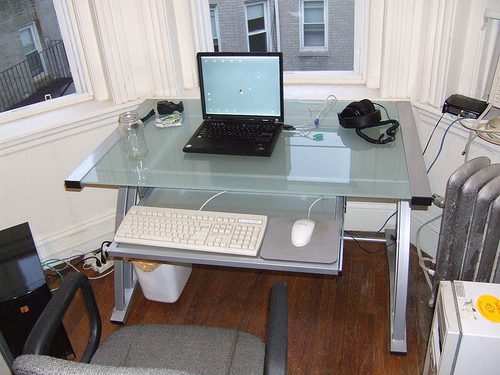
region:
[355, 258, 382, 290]
Dark brown wood grain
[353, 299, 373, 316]
Dark brown wood grain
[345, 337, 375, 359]
Dark brown wood grain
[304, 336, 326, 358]
Dark brown wood grain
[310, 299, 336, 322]
Dark brown wood grain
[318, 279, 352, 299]
Dark brown wood grain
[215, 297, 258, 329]
Dark brown wood grain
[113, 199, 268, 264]
White keyboard with white keys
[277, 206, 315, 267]
White mouse on grey mousepad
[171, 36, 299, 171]
Small black laptop computer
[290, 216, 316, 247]
a white computer mouse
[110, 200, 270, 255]
a white computer keyboard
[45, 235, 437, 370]
part of a brown hardwood floor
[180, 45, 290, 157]
a black laptop computer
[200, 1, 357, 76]
part of a window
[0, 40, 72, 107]
part of a balcony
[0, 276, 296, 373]
a gray and black computer chair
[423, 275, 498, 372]
part of a computer cpu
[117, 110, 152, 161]
a tall clear jar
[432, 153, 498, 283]
part of a gray wall heater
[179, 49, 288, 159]
Black laptop with blue desktop screen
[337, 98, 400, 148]
Pair of black computer headphones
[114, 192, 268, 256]
Corded white computer keyboard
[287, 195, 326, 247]
Corded white computer mouse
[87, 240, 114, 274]
White surge protector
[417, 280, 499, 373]
White central processing unit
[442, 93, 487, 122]
Black internet router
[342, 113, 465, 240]
Long blue ethernet cord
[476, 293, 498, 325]
Oval yellow sticker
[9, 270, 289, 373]
Gray cushion office chair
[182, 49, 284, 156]
black laptop on a gray desk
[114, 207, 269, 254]
keyboard on a keyboard shelf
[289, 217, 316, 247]
mouse connected by wire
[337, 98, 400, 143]
a set of headphones that is not connected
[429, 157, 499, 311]
an old fashioned radiator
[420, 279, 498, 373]
a desktop computer in the floor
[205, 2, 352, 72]
a building visible out the window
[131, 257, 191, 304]
a white waste basket under the desk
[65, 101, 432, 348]
a stark and functional work desk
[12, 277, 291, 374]
office chair on a wooden floor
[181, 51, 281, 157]
a black laptop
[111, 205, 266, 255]
a white keyboard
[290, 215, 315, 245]
a white mouse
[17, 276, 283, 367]
part of a gray desk chair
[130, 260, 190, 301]
a white trash can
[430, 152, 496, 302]
a silver wall radiator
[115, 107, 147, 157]
a clear jar on the table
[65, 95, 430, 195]
the glass desk the laptop is on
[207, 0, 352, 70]
the middle window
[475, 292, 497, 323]
a yellow sticker